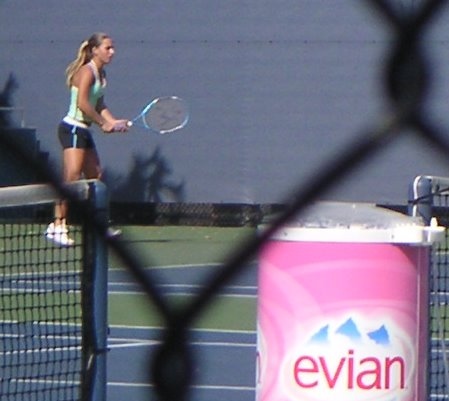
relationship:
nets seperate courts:
[2, 178, 448, 400] [1, 250, 449, 400]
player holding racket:
[46, 33, 130, 247] [127, 94, 191, 136]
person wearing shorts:
[46, 33, 130, 247] [57, 121, 96, 151]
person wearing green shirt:
[46, 33, 130, 247] [62, 61, 109, 130]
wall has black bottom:
[1, 3, 448, 207] [0, 203, 448, 230]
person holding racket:
[46, 33, 130, 247] [127, 94, 191, 136]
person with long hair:
[46, 33, 130, 247] [65, 34, 113, 89]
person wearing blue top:
[46, 33, 130, 247] [62, 61, 109, 130]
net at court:
[1, 176, 107, 400] [0, 319, 448, 400]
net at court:
[413, 176, 449, 400] [1, 252, 448, 304]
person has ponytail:
[46, 33, 130, 247] [63, 40, 90, 88]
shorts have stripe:
[57, 121, 96, 151] [72, 124, 77, 148]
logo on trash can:
[295, 320, 407, 391] [257, 200, 448, 401]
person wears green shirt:
[46, 33, 130, 247] [62, 61, 109, 130]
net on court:
[1, 176, 107, 400] [0, 319, 448, 400]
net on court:
[413, 176, 449, 400] [1, 252, 448, 304]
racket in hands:
[127, 94, 191, 136] [102, 119, 131, 133]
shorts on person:
[57, 121, 96, 151] [46, 33, 130, 247]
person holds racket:
[46, 33, 130, 247] [127, 94, 191, 136]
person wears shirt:
[46, 33, 130, 247] [62, 61, 109, 130]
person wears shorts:
[46, 33, 130, 247] [57, 121, 96, 151]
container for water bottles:
[257, 200, 448, 401] [261, 217, 420, 228]